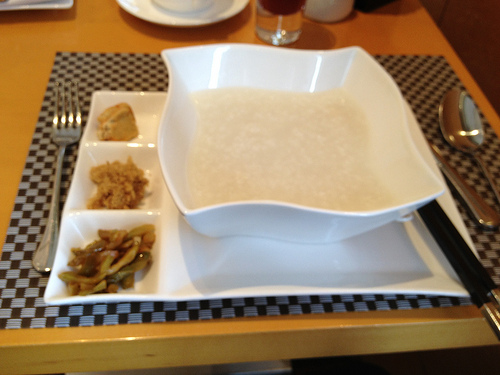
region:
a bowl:
[193, 84, 375, 204]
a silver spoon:
[443, 92, 498, 162]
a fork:
[43, 89, 77, 217]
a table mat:
[63, 53, 140, 84]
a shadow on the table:
[126, 23, 168, 40]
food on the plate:
[99, 105, 151, 139]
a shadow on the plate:
[192, 253, 418, 287]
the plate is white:
[161, 258, 458, 295]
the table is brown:
[169, 323, 454, 353]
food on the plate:
[73, 238, 153, 293]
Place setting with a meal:
[3, 5, 495, 371]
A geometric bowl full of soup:
[155, 39, 445, 239]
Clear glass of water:
[252, 0, 304, 42]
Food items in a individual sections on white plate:
[69, 90, 152, 291]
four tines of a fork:
[45, 78, 84, 143]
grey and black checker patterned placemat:
[46, 48, 158, 90]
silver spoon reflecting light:
[436, 83, 489, 157]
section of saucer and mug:
[112, 0, 249, 30]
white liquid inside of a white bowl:
[159, 40, 434, 229]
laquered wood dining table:
[9, 28, 39, 83]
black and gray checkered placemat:
[0, 47, 499, 332]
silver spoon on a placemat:
[429, 82, 499, 194]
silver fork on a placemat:
[23, 77, 83, 271]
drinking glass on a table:
[250, 2, 305, 44]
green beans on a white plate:
[51, 217, 159, 297]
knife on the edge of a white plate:
[420, 203, 499, 349]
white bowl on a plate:
[136, 40, 456, 253]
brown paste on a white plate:
[91, 100, 138, 143]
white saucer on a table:
[111, 0, 253, 25]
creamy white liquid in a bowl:
[211, 101, 353, 180]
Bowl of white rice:
[156, 35, 448, 227]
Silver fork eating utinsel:
[31, 64, 84, 296]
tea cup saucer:
[108, 1, 268, 36]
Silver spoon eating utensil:
[431, 79, 498, 224]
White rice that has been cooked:
[198, 107, 335, 163]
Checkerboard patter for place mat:
[23, 45, 158, 92]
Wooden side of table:
[0, 324, 440, 368]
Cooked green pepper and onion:
[58, 212, 170, 302]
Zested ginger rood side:
[79, 149, 151, 210]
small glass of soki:
[245, 0, 332, 50]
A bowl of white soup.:
[180, 45, 377, 207]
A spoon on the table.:
[412, 61, 497, 200]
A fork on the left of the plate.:
[47, 76, 75, 273]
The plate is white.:
[75, 108, 326, 333]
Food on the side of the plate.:
[71, 97, 149, 337]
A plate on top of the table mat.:
[41, 38, 497, 303]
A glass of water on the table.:
[252, 5, 329, 42]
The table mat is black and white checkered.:
[45, 32, 153, 89]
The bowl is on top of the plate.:
[125, 36, 446, 289]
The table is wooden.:
[127, 317, 464, 374]